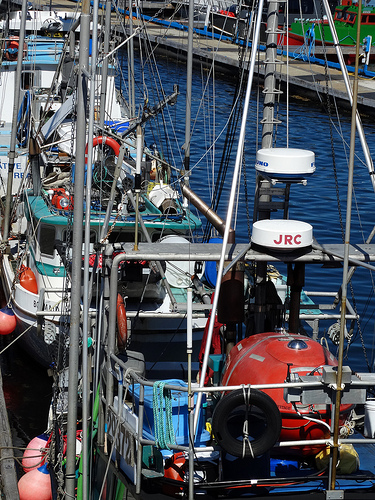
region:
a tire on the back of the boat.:
[210, 384, 283, 460]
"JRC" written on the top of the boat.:
[263, 230, 303, 249]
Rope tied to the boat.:
[139, 382, 177, 453]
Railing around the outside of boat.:
[101, 354, 165, 475]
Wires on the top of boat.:
[94, 23, 192, 212]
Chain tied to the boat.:
[347, 292, 373, 361]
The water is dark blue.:
[159, 73, 311, 171]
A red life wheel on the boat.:
[84, 134, 119, 179]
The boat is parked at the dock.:
[147, 7, 374, 75]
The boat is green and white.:
[23, 202, 188, 342]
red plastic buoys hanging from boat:
[18, 416, 66, 493]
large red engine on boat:
[216, 321, 348, 443]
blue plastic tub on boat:
[129, 378, 204, 439]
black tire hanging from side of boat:
[212, 385, 288, 458]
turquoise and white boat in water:
[13, 105, 228, 345]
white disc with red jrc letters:
[250, 218, 318, 249]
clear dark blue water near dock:
[111, 49, 369, 383]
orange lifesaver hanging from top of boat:
[83, 135, 122, 177]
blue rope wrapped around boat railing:
[150, 377, 184, 454]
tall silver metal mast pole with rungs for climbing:
[255, 2, 294, 283]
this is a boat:
[3, 165, 372, 497]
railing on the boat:
[97, 212, 372, 368]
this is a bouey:
[7, 412, 93, 498]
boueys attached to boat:
[6, 360, 129, 499]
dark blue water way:
[160, 60, 358, 228]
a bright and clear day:
[15, 62, 368, 495]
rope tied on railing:
[143, 372, 197, 471]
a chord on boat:
[203, 376, 292, 475]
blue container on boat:
[108, 361, 212, 481]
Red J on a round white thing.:
[273, 233, 282, 244]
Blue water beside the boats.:
[123, 55, 373, 367]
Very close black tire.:
[212, 391, 282, 460]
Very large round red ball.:
[222, 330, 354, 460]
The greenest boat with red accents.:
[291, 2, 374, 48]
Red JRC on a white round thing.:
[274, 233, 302, 245]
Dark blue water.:
[114, 47, 373, 370]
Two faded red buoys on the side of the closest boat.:
[14, 433, 53, 498]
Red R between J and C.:
[283, 234, 291, 246]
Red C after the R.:
[293, 235, 302, 245]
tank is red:
[17, 263, 37, 294]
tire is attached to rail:
[210, 389, 283, 460]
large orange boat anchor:
[16, 458, 58, 498]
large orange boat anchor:
[20, 431, 55, 469]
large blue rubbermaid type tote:
[125, 377, 205, 441]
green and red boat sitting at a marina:
[271, 2, 372, 72]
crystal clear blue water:
[109, 37, 374, 371]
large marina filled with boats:
[0, 0, 373, 498]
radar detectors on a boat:
[247, 217, 315, 251]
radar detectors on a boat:
[252, 145, 318, 181]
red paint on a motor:
[232, 327, 342, 378]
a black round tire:
[211, 371, 283, 467]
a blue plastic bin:
[127, 365, 204, 452]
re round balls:
[17, 461, 55, 498]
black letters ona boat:
[27, 295, 67, 319]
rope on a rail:
[147, 375, 183, 460]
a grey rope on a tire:
[224, 378, 259, 466]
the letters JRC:
[266, 232, 307, 247]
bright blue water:
[161, 90, 272, 144]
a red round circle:
[80, 125, 119, 177]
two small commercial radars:
[248, 132, 332, 274]